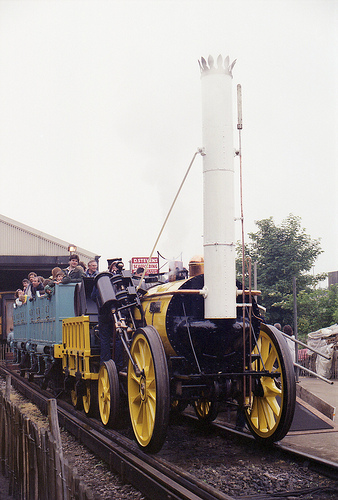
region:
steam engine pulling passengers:
[4, 242, 312, 458]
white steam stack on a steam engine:
[191, 43, 254, 333]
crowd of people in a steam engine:
[13, 253, 112, 315]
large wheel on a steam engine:
[118, 318, 171, 467]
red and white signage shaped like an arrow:
[131, 253, 168, 275]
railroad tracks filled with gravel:
[153, 456, 269, 498]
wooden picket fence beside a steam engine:
[6, 393, 79, 490]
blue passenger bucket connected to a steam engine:
[9, 294, 72, 360]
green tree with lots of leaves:
[247, 214, 316, 322]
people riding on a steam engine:
[11, 29, 307, 451]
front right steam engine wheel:
[126, 324, 168, 453]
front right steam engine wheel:
[261, 325, 294, 445]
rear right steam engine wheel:
[97, 357, 118, 427]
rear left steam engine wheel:
[194, 397, 221, 420]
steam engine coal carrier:
[63, 280, 96, 416]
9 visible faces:
[13, 251, 154, 307]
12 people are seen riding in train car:
[11, 252, 146, 308]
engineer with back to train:
[6, 323, 17, 357]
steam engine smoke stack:
[195, 50, 238, 322]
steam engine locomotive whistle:
[235, 81, 255, 408]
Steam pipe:
[177, 49, 258, 322]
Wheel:
[123, 326, 171, 449]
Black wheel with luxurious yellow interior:
[243, 325, 288, 435]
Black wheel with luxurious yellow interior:
[96, 361, 118, 425]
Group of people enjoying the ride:
[8, 229, 126, 295]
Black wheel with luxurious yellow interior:
[72, 371, 87, 407]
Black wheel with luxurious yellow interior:
[64, 371, 72, 394]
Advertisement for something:
[126, 248, 162, 275]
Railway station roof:
[0, 209, 99, 268]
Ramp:
[269, 314, 336, 419]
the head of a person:
[108, 257, 119, 270]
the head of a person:
[85, 259, 98, 270]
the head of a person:
[68, 253, 81, 268]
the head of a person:
[53, 270, 65, 279]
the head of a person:
[48, 264, 62, 275]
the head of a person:
[39, 280, 54, 296]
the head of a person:
[26, 270, 35, 279]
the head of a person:
[30, 274, 42, 287]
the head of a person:
[21, 277, 27, 288]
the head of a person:
[12, 286, 22, 296]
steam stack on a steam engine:
[186, 47, 281, 325]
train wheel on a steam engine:
[115, 319, 170, 457]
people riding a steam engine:
[10, 238, 280, 439]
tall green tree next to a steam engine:
[247, 205, 327, 322]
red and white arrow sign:
[129, 250, 180, 282]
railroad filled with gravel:
[188, 438, 314, 494]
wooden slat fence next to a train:
[5, 393, 76, 499]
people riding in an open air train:
[13, 267, 84, 301]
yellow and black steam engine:
[109, 268, 293, 460]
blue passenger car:
[10, 295, 77, 343]